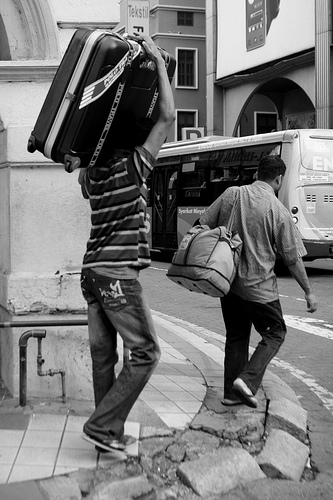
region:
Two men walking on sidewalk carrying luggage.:
[23, 29, 319, 459]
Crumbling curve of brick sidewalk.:
[120, 420, 328, 498]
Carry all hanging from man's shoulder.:
[161, 178, 260, 305]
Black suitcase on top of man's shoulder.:
[17, 29, 173, 176]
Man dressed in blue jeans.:
[216, 286, 290, 401]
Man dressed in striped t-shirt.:
[74, 147, 164, 284]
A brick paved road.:
[153, 280, 216, 337]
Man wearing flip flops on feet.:
[219, 380, 266, 409]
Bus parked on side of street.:
[151, 127, 330, 266]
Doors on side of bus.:
[143, 161, 186, 259]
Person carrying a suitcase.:
[20, 18, 279, 340]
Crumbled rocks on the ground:
[139, 424, 220, 492]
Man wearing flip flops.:
[192, 372, 281, 420]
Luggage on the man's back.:
[173, 160, 291, 301]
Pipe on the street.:
[17, 326, 110, 398]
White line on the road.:
[279, 265, 326, 345]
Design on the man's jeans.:
[97, 274, 157, 318]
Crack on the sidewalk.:
[176, 348, 237, 421]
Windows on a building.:
[166, 5, 220, 95]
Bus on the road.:
[197, 135, 330, 276]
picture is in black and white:
[1, 0, 331, 489]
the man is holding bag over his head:
[13, 6, 183, 213]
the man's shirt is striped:
[55, 157, 173, 266]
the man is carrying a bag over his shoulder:
[178, 179, 263, 296]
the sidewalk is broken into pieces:
[47, 387, 324, 496]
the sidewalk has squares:
[0, 405, 150, 489]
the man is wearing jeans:
[60, 264, 163, 440]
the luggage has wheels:
[8, 101, 105, 188]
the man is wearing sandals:
[198, 368, 297, 450]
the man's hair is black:
[247, 146, 289, 184]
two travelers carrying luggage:
[43, 27, 314, 357]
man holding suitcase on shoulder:
[25, 18, 183, 193]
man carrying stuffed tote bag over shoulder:
[160, 144, 304, 317]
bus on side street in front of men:
[131, 122, 330, 283]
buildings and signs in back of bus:
[112, 6, 329, 148]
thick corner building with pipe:
[7, 6, 104, 407]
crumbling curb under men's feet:
[79, 360, 316, 495]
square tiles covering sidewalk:
[27, 331, 212, 482]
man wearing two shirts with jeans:
[77, 139, 169, 441]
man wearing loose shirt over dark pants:
[189, 135, 315, 404]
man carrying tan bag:
[166, 153, 319, 407]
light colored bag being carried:
[166, 223, 246, 301]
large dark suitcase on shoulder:
[25, 26, 178, 173]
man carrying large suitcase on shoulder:
[26, 27, 178, 457]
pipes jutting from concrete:
[16, 327, 70, 409]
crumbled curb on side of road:
[178, 383, 317, 499]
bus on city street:
[144, 127, 332, 278]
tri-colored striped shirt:
[79, 145, 153, 281]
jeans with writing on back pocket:
[74, 267, 164, 440]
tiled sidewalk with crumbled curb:
[4, 410, 236, 499]